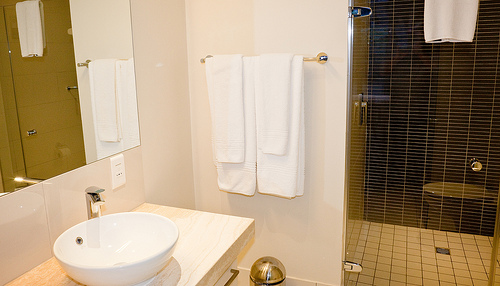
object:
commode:
[419, 180, 497, 224]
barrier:
[351, 0, 496, 286]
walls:
[203, 0, 342, 284]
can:
[251, 254, 286, 283]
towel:
[9, 0, 50, 60]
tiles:
[367, 230, 430, 282]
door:
[340, 2, 499, 284]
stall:
[348, 0, 493, 284]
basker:
[251, 254, 286, 285]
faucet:
[83, 186, 113, 221]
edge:
[1, 141, 151, 196]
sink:
[52, 212, 180, 286]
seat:
[421, 178, 487, 220]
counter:
[130, 203, 258, 286]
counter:
[2, 254, 67, 286]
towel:
[253, 52, 305, 201]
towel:
[201, 52, 261, 200]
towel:
[419, 0, 480, 45]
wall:
[0, 4, 192, 269]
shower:
[350, 0, 499, 286]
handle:
[354, 93, 370, 125]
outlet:
[109, 154, 127, 190]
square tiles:
[347, 215, 497, 284]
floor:
[236, 216, 499, 284]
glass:
[342, 1, 499, 282]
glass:
[2, 1, 142, 196]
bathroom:
[0, 0, 499, 286]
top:
[249, 255, 283, 277]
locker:
[11, 202, 263, 286]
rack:
[198, 52, 330, 65]